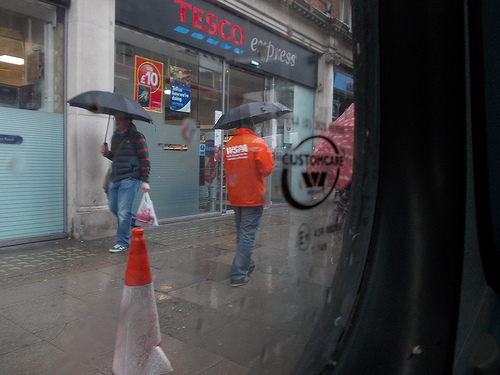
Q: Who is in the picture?
A: Two men.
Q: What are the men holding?
A: Umbrellas.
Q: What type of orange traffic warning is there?
A: A cone.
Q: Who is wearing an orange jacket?
A: The man walking away.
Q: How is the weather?
A: Rainy.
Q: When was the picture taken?
A: Afternoon.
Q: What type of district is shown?
A: Shopping.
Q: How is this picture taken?
A: Through a window.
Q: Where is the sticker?
A: Window.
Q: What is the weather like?
A: Rainy.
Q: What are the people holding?
A: Umbrellas.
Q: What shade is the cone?
A: Orange and white.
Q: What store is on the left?
A: TESCO Express.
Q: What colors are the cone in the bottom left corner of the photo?
A: Red, White.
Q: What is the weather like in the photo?
A: Raining.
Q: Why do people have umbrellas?
A: Stay dry.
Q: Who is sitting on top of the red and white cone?
A: No one.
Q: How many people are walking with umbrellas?
A: Two.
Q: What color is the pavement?
A: Grey.